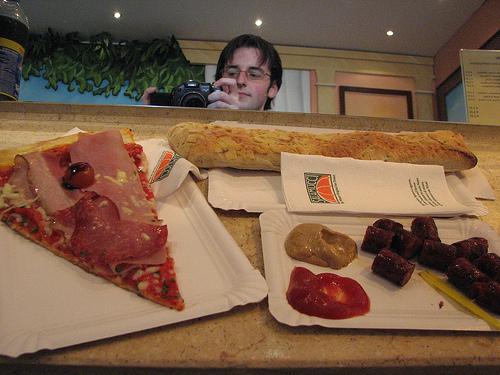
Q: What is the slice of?
A: Pizza.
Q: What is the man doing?
A: Taking a picture.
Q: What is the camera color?
A: Black.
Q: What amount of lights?
A: Three.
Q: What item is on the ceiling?
A: Lights.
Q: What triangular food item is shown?
A: A pizza.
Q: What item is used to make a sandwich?
A: Bread.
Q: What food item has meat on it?
A: Pizza.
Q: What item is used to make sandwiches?
A: Bread.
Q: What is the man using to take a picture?
A: A camera.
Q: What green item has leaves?
A: A tree.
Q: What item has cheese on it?
A: A pizza.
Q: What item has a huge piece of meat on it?
A: A pizza.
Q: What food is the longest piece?
A: Bread.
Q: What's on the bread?
A: Cheese.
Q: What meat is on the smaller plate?
A: Sausages.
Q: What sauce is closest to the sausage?
A: Mustard.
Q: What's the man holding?
A: Camera.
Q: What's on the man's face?
A: Glasses.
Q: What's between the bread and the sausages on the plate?
A: Napkin.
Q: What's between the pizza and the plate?
A: Napkin.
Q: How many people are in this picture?
A: One.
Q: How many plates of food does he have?
A: Three.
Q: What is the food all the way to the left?
A: Pizza.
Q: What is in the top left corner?
A: A soda.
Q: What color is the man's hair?
A: Brown.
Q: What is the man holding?
A: A camera.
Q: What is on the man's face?
A: Glasses.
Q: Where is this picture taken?
A: A restaurant.